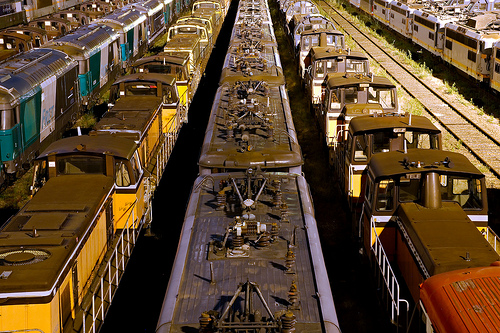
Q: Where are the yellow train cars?
A: On the left.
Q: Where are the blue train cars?
A: On the far left.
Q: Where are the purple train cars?
A: In the center.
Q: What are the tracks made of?
A: Metal.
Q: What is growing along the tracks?
A: Grass.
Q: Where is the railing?
A: On the sides of the train cars.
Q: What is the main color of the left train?
A: Yellow.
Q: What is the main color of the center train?
A: Gray.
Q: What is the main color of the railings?
A: Brown.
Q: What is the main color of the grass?
A: Green.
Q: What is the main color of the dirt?
A: Brown.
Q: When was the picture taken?
A: In the day.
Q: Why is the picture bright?
A: It's sunny.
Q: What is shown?
A: A train depot.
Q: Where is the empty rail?
A: The right side.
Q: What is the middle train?
A: Electric.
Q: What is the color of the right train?
A: White.